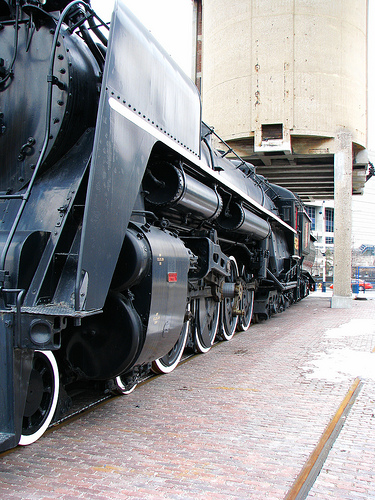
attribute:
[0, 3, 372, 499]
picture — daytime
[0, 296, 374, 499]
ground — bricks, red brick, dirty, walkway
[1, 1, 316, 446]
train — on tracks, black, parked, metal, displayed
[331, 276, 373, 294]
car — red, parked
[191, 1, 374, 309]
siloh — large, oil tank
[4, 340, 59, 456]
wheel — white rimmed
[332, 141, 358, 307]
pillar — steel, large, concrete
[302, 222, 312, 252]
sign — red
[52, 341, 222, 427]
rail — part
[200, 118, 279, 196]
rail — metal, black, hand grip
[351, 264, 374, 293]
fence — blue, tall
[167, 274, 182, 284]
red spot — metal